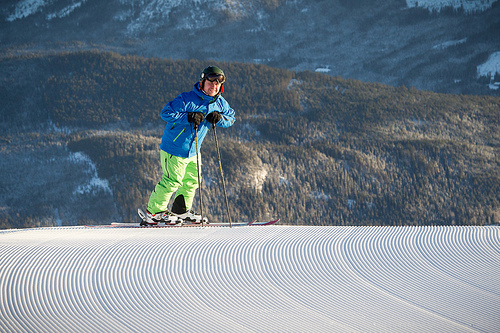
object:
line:
[257, 226, 330, 321]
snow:
[131, 233, 479, 304]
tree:
[280, 121, 314, 148]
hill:
[233, 4, 495, 127]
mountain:
[26, 35, 499, 226]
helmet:
[200, 65, 226, 83]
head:
[199, 66, 225, 97]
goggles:
[204, 74, 225, 83]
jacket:
[158, 82, 236, 158]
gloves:
[187, 111, 205, 124]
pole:
[194, 119, 204, 228]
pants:
[146, 150, 203, 214]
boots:
[170, 210, 209, 224]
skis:
[111, 218, 256, 228]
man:
[145, 66, 235, 225]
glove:
[205, 111, 220, 124]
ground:
[30, 211, 455, 314]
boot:
[144, 210, 183, 225]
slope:
[211, 217, 498, 230]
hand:
[205, 111, 220, 124]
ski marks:
[413, 226, 499, 301]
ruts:
[3, 225, 483, 328]